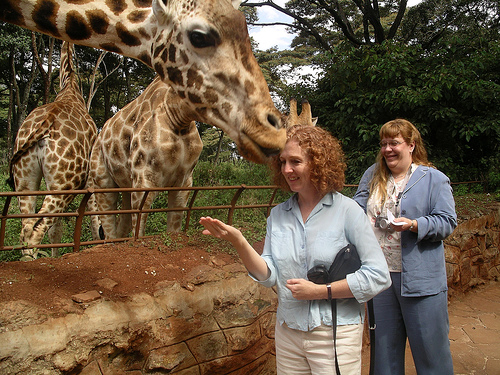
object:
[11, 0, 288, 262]
giraffe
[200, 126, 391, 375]
woman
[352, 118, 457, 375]
woman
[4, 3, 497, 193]
trees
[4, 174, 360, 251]
fence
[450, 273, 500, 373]
pathway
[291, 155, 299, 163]
eye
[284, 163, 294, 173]
nose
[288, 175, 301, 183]
mouth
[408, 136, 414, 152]
ear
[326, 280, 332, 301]
watch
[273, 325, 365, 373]
pants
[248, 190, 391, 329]
shirt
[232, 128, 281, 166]
mouth